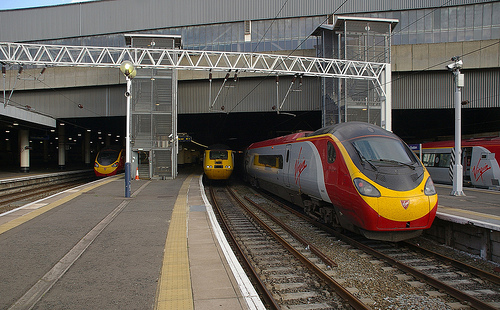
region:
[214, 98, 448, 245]
this is a train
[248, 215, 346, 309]
this is a railway track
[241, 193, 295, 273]
this is a railway track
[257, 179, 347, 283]
this is a railway track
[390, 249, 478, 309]
this is a railway track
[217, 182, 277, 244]
this is a railway track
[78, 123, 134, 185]
Train coming out of a tunnel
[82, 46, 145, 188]
Red and yellow train coming out of a tunnel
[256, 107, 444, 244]
Red, orange, black and gray train car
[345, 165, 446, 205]
Two headlights on a train car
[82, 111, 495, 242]
Four trains coming out of a tunnel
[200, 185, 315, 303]
Train tracks next to a platform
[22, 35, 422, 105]
Electrical wires above train tracks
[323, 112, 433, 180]
Train windshield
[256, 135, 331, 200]
The right side of a train car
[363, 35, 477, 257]
Video camera next a train track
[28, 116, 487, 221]
four trains in a tunnel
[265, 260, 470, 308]
two sets of train tracks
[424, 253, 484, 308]
a set of train tracks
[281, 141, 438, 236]
a red, yellow and silver train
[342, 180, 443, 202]
headlights on a train car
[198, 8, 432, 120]
electrical wires hanging from post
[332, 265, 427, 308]
gravel between sets of train tracks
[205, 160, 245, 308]
a white line painted on a plat form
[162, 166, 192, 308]
a yellow line painted on a plat form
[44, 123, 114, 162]
several lights hanging from a cieling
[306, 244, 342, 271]
broken line on track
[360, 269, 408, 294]
gravel on the track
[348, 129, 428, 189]
large front windows on train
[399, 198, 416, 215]
small red symbol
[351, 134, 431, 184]
large black windshield wiper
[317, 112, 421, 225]
sleek modern front on train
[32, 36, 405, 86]
overhead silver bridge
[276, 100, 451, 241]
large train on the track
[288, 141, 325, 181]
red words on side of train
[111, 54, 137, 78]
tall lights on the platform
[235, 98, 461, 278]
train approaching a rail station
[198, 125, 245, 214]
train approaching a rail station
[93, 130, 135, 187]
train approaching a rail station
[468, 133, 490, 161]
train approaching a rail station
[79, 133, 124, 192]
train approaching a rail station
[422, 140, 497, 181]
train approaching a rail station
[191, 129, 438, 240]
train approaching a rail station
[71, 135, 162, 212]
train approaching a rail station